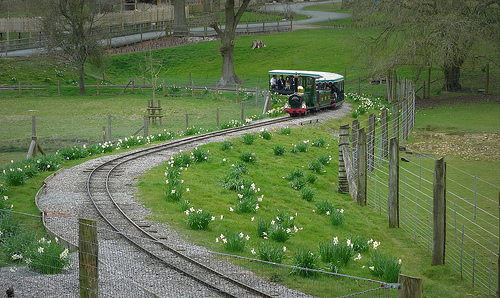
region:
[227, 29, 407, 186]
a train on the tracks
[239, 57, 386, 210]
a train on a train track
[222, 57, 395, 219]
a small train on a train track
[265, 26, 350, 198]
a smal train on a track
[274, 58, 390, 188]
a passenger train on the track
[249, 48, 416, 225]
a passenger train on train tracks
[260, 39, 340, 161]
a track with a train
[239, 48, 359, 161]
a train track with train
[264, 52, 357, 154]
a track with a short train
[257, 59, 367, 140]
small train on track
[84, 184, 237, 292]
track is dark grey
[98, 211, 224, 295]
grey gravel between tracks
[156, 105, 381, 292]
green flowers near track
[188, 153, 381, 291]
green grass among flowers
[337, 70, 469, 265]
fence posts are brown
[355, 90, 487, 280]
metal wire between posts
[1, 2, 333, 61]
grey road behind track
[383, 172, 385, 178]
edge of a fence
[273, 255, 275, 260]
part of a fence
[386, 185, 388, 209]
part of a fence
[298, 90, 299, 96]
part of a train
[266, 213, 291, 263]
part of a lawn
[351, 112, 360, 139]
part of a fence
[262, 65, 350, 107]
A trolly transporting people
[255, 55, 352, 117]
A green and red train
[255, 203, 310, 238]
A patch of white flowers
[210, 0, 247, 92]
A tree missing limbs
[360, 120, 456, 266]
A fence with wooden posts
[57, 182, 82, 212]
A gravel filled path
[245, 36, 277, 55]
A tree stump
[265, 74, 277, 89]
A man with a white shirt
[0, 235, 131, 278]
a fence with metal chainlink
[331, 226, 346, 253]
white flower on ground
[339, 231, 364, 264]
white flower on ground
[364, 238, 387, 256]
white flower on ground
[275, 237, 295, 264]
white flower on ground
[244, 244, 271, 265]
white flower on ground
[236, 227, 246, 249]
white flower on ground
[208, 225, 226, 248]
white flower on ground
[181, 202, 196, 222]
white flower on ground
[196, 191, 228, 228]
white flower on ground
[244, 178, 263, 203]
white flower on ground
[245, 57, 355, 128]
A train is on the tracks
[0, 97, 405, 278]
White flowers in the grass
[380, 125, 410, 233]
A brown wooden post